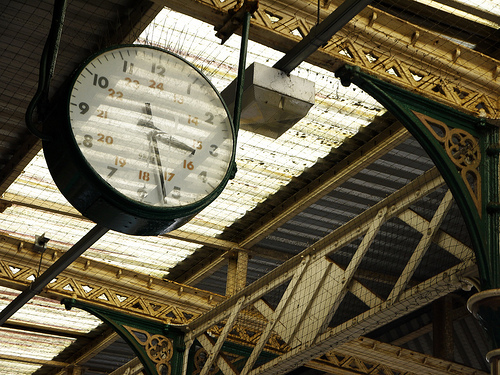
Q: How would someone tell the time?
A: Look at the clock.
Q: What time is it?
A: 3:27.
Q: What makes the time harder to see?
A: The reflection on the clock.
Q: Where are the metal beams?
A: On the ceiling.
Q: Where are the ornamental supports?
A: At the joint of the beams.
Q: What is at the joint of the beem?
A: A wrought iron molding.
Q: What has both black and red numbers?
A: The clock.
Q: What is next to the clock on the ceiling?
A: A light fixture.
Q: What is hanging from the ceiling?
A: A clock.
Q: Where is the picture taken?
A: A trainstation.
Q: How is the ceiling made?
A: Of metal.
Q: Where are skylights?
A: The ceiling.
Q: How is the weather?
A: Sunny.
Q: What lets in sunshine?
A: The skylights.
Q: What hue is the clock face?
A: White.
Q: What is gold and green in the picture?
A: The rafters.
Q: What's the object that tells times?
A: Clock.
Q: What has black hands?
A: Clock.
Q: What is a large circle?
A: Clock.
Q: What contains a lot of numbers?
A: Clock.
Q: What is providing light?
A: Sunlight.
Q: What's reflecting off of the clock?
A: Sunlight.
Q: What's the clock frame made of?
A: Metal.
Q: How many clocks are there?
A: 1.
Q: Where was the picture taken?
A: In the building.